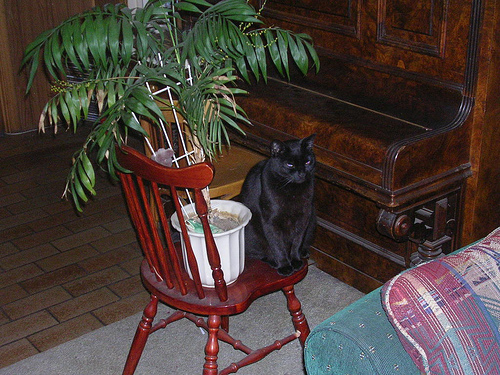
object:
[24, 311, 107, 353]
tile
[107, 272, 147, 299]
tile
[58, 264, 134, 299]
tile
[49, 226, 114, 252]
tile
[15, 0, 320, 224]
palm tree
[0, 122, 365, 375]
floor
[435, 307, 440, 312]
symbols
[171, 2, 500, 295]
brown piano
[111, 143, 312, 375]
chair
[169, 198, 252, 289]
pot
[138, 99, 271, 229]
bench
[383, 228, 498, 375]
cushion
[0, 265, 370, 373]
carpet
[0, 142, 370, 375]
ground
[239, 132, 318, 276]
black cat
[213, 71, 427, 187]
cover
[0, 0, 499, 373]
living room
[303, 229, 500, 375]
sofa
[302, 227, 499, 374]
arm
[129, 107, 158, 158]
wire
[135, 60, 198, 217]
wire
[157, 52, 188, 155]
wire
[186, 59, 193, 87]
wire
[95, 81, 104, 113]
leaf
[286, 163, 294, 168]
eye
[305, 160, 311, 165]
eye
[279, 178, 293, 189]
whiskers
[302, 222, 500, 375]
couch